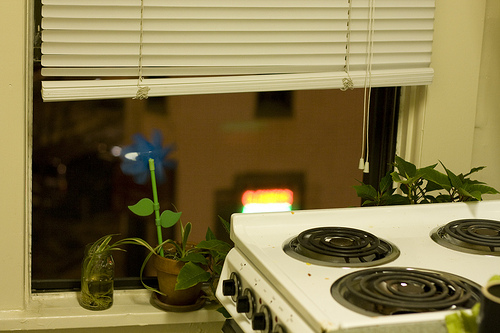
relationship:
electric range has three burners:
[208, 193, 500, 333] [282, 218, 499, 319]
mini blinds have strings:
[41, 0, 436, 104] [358, 1, 374, 175]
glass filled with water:
[73, 243, 117, 312] [77, 274, 114, 310]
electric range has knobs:
[208, 193, 500, 333] [222, 272, 286, 333]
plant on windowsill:
[78, 232, 157, 307] [1, 300, 226, 332]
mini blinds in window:
[41, 0, 436, 104] [31, 1, 401, 296]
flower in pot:
[121, 130, 183, 259] [151, 243, 213, 313]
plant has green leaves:
[354, 152, 500, 207] [352, 152, 499, 207]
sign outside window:
[240, 187, 293, 214] [31, 1, 401, 296]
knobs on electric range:
[222, 272, 286, 333] [208, 193, 500, 333]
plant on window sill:
[67, 230, 161, 314] [0, 300, 229, 331]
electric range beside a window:
[208, 193, 500, 333] [31, 1, 401, 296]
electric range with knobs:
[208, 193, 500, 333] [222, 272, 286, 333]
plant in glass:
[78, 232, 157, 307] [78, 244, 114, 312]